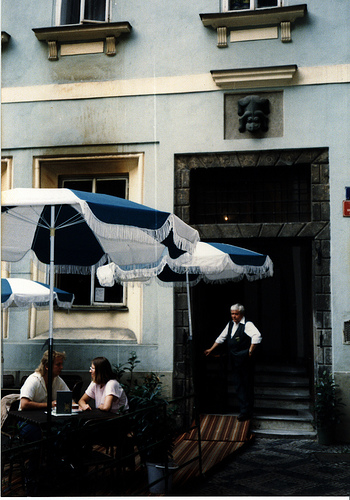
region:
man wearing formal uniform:
[206, 288, 269, 428]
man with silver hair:
[205, 298, 268, 426]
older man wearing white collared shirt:
[200, 298, 266, 435]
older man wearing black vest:
[193, 297, 276, 424]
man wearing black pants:
[204, 298, 268, 427]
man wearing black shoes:
[206, 299, 269, 424]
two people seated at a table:
[12, 336, 140, 481]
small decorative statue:
[227, 96, 280, 142]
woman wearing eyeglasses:
[69, 352, 141, 477]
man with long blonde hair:
[22, 346, 79, 489]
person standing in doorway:
[201, 300, 262, 424]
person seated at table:
[75, 354, 132, 417]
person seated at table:
[18, 349, 75, 418]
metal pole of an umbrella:
[42, 227, 60, 409]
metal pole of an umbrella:
[186, 270, 192, 347]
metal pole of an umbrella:
[0, 312, 6, 412]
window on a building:
[41, 261, 137, 310]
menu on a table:
[53, 389, 75, 417]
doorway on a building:
[173, 217, 338, 439]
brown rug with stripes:
[139, 405, 259, 497]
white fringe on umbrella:
[82, 199, 198, 251]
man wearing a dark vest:
[200, 301, 265, 421]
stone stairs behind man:
[219, 360, 313, 436]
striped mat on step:
[188, 411, 249, 440]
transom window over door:
[187, 164, 314, 225]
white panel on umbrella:
[6, 277, 51, 299]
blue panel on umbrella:
[70, 189, 170, 229]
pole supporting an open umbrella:
[48, 210, 56, 496]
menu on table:
[56, 390, 72, 413]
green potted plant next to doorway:
[311, 363, 348, 445]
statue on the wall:
[231, 88, 278, 142]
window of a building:
[38, 162, 138, 318]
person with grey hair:
[203, 301, 261, 427]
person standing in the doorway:
[205, 298, 264, 435]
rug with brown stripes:
[131, 403, 260, 499]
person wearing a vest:
[200, 298, 261, 429]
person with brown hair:
[75, 354, 128, 418]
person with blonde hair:
[10, 346, 81, 414]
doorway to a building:
[165, 147, 334, 431]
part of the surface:
[272, 421, 279, 436]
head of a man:
[228, 311, 251, 321]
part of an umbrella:
[19, 295, 28, 305]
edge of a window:
[111, 292, 132, 305]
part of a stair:
[299, 396, 321, 418]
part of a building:
[292, 107, 302, 111]